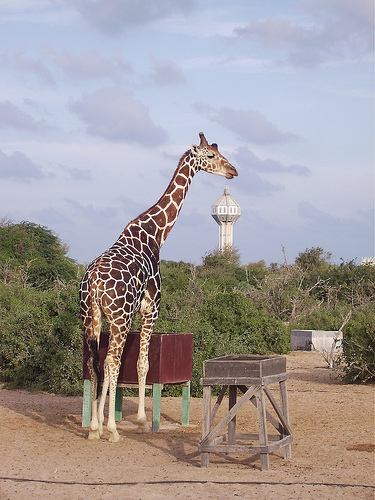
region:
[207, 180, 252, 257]
tall white tower behind giraffe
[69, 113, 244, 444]
brown spotted giraffe standing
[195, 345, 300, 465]
brown box on sand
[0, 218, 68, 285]
tall leafy green tree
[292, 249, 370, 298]
green bushy twig vegetation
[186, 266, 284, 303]
green bushy twig vegetation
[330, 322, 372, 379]
green bushy twig vegetation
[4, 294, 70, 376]
green bushy twig vegetation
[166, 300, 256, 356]
green bushy twig vegetation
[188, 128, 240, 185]
brown spotted giraffe's head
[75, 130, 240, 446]
Large giraffe standing in the sand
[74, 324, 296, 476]
Two large silos for food and water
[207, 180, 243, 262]
Watch tower extended over top of the trees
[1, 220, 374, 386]
Thick vegetative forest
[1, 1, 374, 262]
Cloudy greyish blue sky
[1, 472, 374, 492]
shadow of a rope or wire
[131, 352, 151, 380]
Giraffe's knoby knee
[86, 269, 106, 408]
Giraffe's long tail with a dark hairy tip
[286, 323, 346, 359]
Concrete structure in the middle of the forest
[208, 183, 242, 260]
Tall white building extended into the clouds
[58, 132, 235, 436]
giraffe standing next to trough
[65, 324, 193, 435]
red trough with blue legs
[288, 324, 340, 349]
white cement trough in distance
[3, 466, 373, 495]
dark line in sand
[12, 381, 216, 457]
shadow of giraffe and troughs on sand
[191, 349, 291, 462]
brown trough on wood stand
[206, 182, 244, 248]
white tower in the distance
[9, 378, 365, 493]
dirt giraffe is standing on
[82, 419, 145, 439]
white hooves of giraffe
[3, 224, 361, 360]
bushes and trees around trough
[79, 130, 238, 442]
A very tall giraffe.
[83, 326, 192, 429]
A red and green feeding trough.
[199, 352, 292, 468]
A wooden feeding trough.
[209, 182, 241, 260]
A distant tower.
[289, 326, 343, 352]
A grey square building.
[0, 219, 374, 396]
A large grouping of trees.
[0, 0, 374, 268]
The blue sky with clouds.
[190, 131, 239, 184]
A giraffe head.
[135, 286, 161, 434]
A long giraffe leg.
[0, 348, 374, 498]
Bare dry ground.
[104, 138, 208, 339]
brown giraffe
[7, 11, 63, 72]
white clouds in blue sky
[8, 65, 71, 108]
white clouds in blue sky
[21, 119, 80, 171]
white clouds in blue sky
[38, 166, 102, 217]
white clouds in blue sky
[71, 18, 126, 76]
white clouds in blue sky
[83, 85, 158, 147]
white clouds in blue sky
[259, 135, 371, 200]
white clouds in blue sky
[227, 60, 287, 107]
white clouds in blue sky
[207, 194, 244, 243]
white tower